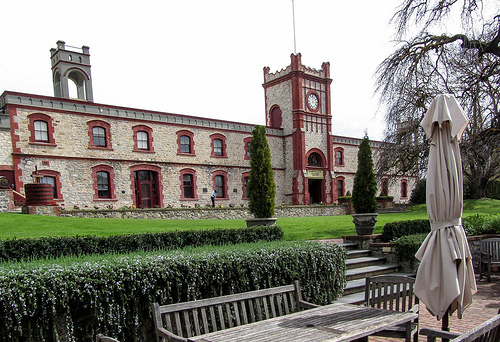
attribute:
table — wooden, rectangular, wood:
[187, 300, 418, 340]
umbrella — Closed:
[419, 93, 477, 325]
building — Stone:
[4, 53, 428, 213]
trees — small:
[239, 126, 384, 214]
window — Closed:
[89, 117, 114, 149]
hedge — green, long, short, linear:
[0, 229, 355, 339]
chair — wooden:
[361, 270, 411, 316]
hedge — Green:
[357, 132, 378, 230]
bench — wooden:
[137, 290, 302, 337]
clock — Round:
[303, 89, 324, 115]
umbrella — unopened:
[408, 87, 479, 340]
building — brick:
[251, 76, 388, 206]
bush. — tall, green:
[251, 126, 277, 217]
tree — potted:
[245, 124, 275, 216]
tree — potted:
[350, 128, 378, 213]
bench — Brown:
[148, 274, 330, 339]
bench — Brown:
[476, 231, 498, 278]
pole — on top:
[292, 0, 297, 53]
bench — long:
[153, 275, 322, 338]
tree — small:
[349, 130, 383, 239]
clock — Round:
[293, 80, 350, 122]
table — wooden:
[155, 272, 417, 337]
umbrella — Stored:
[423, 96, 478, 330]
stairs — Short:
[335, 243, 403, 306]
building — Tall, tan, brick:
[2, 38, 434, 216]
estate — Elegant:
[1, 36, 424, 212]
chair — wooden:
[325, 257, 454, 338]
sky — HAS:
[0, 2, 496, 143]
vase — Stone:
[353, 210, 378, 237]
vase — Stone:
[244, 216, 277, 226]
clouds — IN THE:
[90, 6, 265, 54]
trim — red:
[293, 55, 305, 186]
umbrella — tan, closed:
[398, 91, 472, 322]